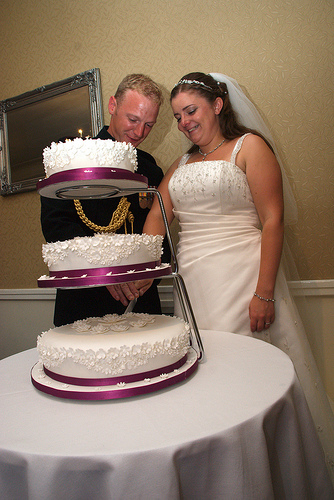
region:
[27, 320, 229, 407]
bottom tier of white wedding cake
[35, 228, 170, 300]
middle tier of white wedding cake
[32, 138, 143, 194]
top tier of white wedding cake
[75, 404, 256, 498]
white tablecloth on cake table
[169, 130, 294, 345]
white wedding dress with sequins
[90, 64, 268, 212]
bride and groom by cake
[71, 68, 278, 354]
bride and groom cutting cake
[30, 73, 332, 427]
bride and groom cutting the wedding cake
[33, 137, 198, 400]
three tier wedding cake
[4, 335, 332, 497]
white cloth on the table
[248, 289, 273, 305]
bracelet on the bride's wrist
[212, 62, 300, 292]
veil the bride is wearing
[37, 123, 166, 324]
black suit jacket man is wearing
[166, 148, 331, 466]
white gown the bride is wearing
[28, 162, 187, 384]
purple ribbons around the cake layers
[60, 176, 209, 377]
silver stand the cake is on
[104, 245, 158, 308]
hands of woman and man holding knife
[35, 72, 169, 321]
man wearing black suit and smiling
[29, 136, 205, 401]
amazing white three tiered wedding cake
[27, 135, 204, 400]
cake has three tiers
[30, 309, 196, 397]
first tier of cake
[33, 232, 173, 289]
second tier of cake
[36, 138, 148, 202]
third tier of cake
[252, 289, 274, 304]
bracelet is worn by woman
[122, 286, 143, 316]
knife is held by man and woman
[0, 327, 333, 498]
table is covered with white linen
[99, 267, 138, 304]
hand holds knife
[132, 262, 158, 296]
hand holds knife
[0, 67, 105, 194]
mirror hangs on wall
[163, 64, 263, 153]
head of a lady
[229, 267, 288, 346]
hand of the lady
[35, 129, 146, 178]
top cake on stack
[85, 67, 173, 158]
head of the man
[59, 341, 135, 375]
white frosting on cake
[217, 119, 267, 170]
strap of the dress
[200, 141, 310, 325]
arm of the lady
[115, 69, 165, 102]
hair on man's head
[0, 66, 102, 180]
mirror on the wall